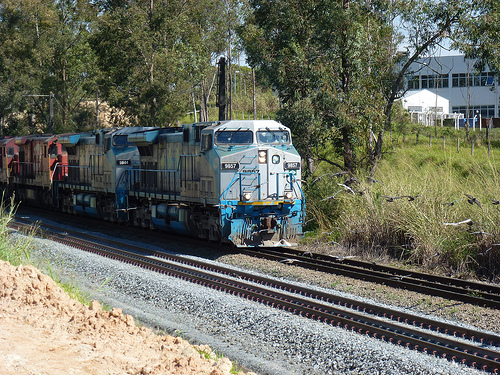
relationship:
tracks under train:
[243, 248, 499, 308] [1, 119, 305, 251]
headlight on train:
[243, 192, 251, 201] [1, 119, 305, 251]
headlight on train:
[285, 191, 294, 201] [1, 119, 305, 251]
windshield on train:
[213, 129, 254, 145] [1, 119, 305, 251]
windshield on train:
[256, 129, 290, 144] [1, 119, 305, 251]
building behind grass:
[392, 37, 499, 128] [302, 123, 498, 282]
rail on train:
[125, 155, 200, 188] [1, 119, 305, 251]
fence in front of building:
[404, 110, 479, 131] [392, 37, 499, 128]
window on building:
[443, 75, 449, 88] [392, 37, 499, 128]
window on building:
[453, 74, 459, 86] [392, 37, 499, 128]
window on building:
[459, 73, 466, 86] [392, 37, 499, 128]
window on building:
[421, 75, 428, 88] [392, 37, 499, 128]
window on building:
[429, 75, 437, 89] [392, 37, 499, 128]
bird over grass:
[464, 191, 485, 208] [302, 123, 498, 282]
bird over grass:
[444, 219, 471, 229] [302, 123, 498, 282]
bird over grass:
[338, 182, 356, 197] [302, 123, 498, 282]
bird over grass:
[444, 219, 471, 229] [336, 181, 356, 196]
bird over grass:
[380, 193, 409, 205] [302, 123, 498, 282]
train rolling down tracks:
[1, 119, 305, 251] [243, 248, 499, 308]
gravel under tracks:
[7, 227, 500, 375] [1, 215, 499, 375]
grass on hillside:
[1, 187, 88, 307] [2, 261, 255, 374]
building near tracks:
[392, 37, 499, 128] [243, 248, 499, 308]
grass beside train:
[302, 123, 498, 282] [1, 119, 305, 251]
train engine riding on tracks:
[129, 121, 305, 247] [243, 248, 499, 308]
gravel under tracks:
[7, 227, 500, 375] [243, 248, 499, 308]